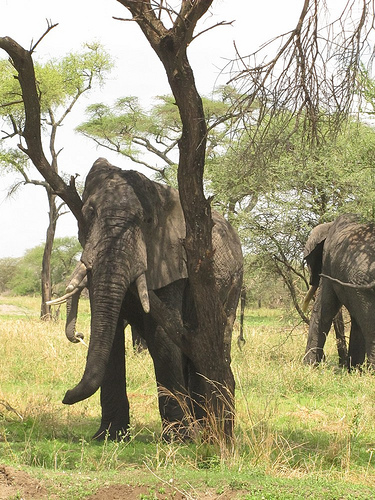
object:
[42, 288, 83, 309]
tusks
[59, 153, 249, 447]
elephant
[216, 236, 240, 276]
wrinkled skin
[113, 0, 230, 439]
tree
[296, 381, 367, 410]
dried grass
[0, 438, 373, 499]
grass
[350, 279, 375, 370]
leg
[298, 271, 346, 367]
leg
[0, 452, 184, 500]
ground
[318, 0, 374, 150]
branch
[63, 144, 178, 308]
train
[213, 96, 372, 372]
tree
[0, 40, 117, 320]
tree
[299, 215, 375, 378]
elephant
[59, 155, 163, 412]
head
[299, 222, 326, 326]
head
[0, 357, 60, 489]
grassy field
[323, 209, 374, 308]
body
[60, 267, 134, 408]
trunk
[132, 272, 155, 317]
tusk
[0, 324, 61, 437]
grass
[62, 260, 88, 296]
tusk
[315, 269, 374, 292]
tail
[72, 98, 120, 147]
leaf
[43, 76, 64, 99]
leaf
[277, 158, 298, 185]
leaf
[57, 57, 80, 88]
leaf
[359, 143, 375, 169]
leaf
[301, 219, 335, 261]
ear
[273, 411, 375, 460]
grass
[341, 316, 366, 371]
right leg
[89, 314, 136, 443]
right leg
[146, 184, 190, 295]
ear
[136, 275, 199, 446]
front leg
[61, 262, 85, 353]
trunk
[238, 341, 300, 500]
grass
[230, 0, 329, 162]
branch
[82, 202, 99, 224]
eyes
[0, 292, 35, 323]
grass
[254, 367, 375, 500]
grass patch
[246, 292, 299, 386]
grass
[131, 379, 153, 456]
grass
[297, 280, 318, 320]
tusk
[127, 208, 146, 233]
eyes